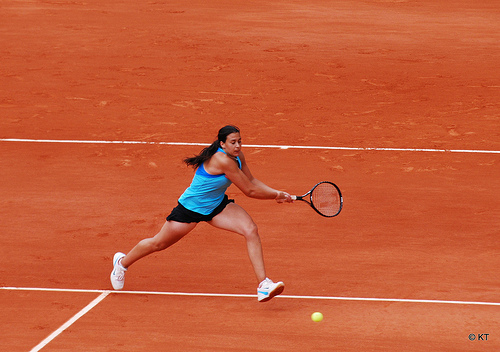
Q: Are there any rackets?
A: Yes, there is a racket.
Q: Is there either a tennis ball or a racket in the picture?
A: Yes, there is a racket.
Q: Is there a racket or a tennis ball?
A: Yes, there is a racket.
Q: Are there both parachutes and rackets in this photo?
A: No, there is a racket but no parachutes.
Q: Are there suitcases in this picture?
A: No, there are no suitcases.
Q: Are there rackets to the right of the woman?
A: Yes, there is a racket to the right of the woman.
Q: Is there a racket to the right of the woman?
A: Yes, there is a racket to the right of the woman.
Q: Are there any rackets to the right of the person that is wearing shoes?
A: Yes, there is a racket to the right of the woman.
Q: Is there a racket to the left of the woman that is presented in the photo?
A: No, the racket is to the right of the woman.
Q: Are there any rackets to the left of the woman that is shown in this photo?
A: No, the racket is to the right of the woman.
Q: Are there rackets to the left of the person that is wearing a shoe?
A: No, the racket is to the right of the woman.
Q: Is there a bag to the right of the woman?
A: No, there is a racket to the right of the woman.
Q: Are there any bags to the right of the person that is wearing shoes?
A: No, there is a racket to the right of the woman.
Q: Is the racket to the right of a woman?
A: Yes, the racket is to the right of a woman.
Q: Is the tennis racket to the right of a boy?
A: No, the tennis racket is to the right of a woman.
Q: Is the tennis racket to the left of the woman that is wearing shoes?
A: No, the tennis racket is to the right of the woman.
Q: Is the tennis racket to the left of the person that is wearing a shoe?
A: No, the tennis racket is to the right of the woman.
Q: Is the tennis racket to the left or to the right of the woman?
A: The tennis racket is to the right of the woman.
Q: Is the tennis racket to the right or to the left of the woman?
A: The tennis racket is to the right of the woman.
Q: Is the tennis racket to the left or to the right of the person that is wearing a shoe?
A: The tennis racket is to the right of the woman.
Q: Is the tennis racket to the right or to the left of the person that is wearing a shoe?
A: The tennis racket is to the right of the woman.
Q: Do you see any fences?
A: No, there are no fences.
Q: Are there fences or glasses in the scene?
A: No, there are no fences or glasses.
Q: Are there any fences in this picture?
A: No, there are no fences.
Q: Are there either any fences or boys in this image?
A: No, there are no fences or boys.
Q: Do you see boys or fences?
A: No, there are no fences or boys.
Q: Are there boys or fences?
A: No, there are no fences or boys.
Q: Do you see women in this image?
A: Yes, there is a woman.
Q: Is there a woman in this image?
A: Yes, there is a woman.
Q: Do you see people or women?
A: Yes, there is a woman.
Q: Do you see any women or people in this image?
A: Yes, there is a woman.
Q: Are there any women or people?
A: Yes, there is a woman.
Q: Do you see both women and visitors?
A: No, there is a woman but no visitors.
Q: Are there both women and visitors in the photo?
A: No, there is a woman but no visitors.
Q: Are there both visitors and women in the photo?
A: No, there is a woman but no visitors.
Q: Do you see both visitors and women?
A: No, there is a woman but no visitors.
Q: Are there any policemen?
A: No, there are no policemen.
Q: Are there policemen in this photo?
A: No, there are no policemen.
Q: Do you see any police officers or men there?
A: No, there are no police officers or men.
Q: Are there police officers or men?
A: No, there are no police officers or men.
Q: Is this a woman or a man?
A: This is a woman.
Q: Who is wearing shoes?
A: The woman is wearing shoes.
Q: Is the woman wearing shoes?
A: Yes, the woman is wearing shoes.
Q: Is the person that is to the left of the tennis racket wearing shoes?
A: Yes, the woman is wearing shoes.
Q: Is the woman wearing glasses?
A: No, the woman is wearing shoes.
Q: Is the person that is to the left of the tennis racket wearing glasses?
A: No, the woman is wearing shoes.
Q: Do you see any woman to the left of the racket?
A: Yes, there is a woman to the left of the racket.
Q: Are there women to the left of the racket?
A: Yes, there is a woman to the left of the racket.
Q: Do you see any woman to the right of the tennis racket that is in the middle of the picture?
A: No, the woman is to the left of the tennis racket.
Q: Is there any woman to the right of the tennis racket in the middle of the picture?
A: No, the woman is to the left of the tennis racket.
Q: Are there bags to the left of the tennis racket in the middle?
A: No, there is a woman to the left of the racket.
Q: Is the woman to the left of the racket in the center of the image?
A: Yes, the woman is to the left of the racket.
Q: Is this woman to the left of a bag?
A: No, the woman is to the left of the racket.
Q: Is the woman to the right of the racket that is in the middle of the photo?
A: No, the woman is to the left of the racket.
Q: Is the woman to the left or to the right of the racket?
A: The woman is to the left of the racket.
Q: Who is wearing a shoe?
A: The woman is wearing a shoe.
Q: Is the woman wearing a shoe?
A: Yes, the woman is wearing a shoe.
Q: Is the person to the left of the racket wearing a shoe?
A: Yes, the woman is wearing a shoe.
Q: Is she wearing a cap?
A: No, the woman is wearing a shoe.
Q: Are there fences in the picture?
A: No, there are no fences.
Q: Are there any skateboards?
A: No, there are no skateboards.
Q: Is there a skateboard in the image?
A: No, there are no skateboards.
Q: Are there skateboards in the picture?
A: No, there are no skateboards.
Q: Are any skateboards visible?
A: No, there are no skateboards.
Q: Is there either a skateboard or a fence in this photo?
A: No, there are no skateboards or fences.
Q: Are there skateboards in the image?
A: No, there are no skateboards.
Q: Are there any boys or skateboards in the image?
A: No, there are no skateboards or boys.